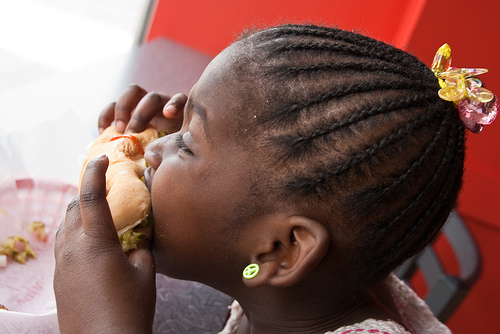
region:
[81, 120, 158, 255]
food in a girl's hand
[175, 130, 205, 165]
a girl's left eye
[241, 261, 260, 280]
earring in a girl's ear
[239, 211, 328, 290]
girl's left ear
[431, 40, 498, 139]
barrettes in a girl's hair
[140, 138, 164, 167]
nose of a girl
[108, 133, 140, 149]
ketchup on a hot dog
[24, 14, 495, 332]
This is a child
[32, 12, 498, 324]
This is a child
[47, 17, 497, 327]
This is a child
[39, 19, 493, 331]
This is a child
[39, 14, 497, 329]
This is a child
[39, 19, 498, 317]
This is a child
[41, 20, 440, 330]
This is a child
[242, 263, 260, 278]
the earring in the girl's ear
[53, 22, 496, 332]
the little girl eating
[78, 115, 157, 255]
the food the girl is eating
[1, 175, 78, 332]
the empty food basket in front of the girl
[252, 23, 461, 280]
the braids on the girl's head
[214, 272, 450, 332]
the clothes on the girl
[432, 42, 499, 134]
the hair barrette in the girl's hair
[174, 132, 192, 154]
the eyelash on the girl's face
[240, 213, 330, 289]
the ear on the girl's head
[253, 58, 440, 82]
the braid on the girl's head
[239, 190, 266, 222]
small section of black hair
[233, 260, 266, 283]
tiny yellow circle earring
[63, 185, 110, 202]
small marks on girl's knuckles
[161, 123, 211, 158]
girl's long luxurious eyelash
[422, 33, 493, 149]
pink and yellow ribbon in hair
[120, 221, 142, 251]
small smattering of green relish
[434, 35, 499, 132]
Colorful clip in girl's hair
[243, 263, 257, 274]
Peace sign earring in girl's ear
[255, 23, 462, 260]
Brown hair in cornrows